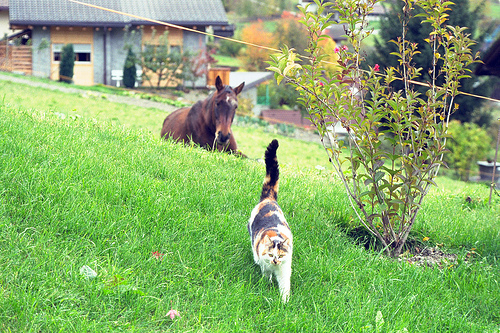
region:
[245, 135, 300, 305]
A black/white/orange cat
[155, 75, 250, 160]
A brown/black horse resting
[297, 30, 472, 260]
A small shrub/bush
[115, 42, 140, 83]
A small pine tree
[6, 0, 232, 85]
A brown/black house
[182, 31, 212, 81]
A small red leaved tree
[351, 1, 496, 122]
A very large pine tree in the backround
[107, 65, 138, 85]
A white bench behind the pine tree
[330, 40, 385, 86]
A few pink flowers on a shrub/bush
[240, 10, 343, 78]
A tree with multiple leaf colors in the backround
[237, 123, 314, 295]
orange black and white cat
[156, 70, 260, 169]
brown and white horse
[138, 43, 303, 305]
horse and cat in green grass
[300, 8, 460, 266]
green bush in green grass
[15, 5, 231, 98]
tan and grey house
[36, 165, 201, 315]
green grass on the ground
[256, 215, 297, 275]
head of a tabby cat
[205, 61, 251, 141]
head of a brown horse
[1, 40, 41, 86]
brown wooden fence attached to a house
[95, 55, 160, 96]
white wooden bench in front of a house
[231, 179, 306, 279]
The cat is calico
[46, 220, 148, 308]
The grass has leaves in it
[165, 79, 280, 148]
The horse is laying down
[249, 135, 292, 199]
The cat's tail is black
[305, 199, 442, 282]
The bush is growing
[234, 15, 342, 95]
The leaves in the tree are many colors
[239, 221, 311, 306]
The cat is walking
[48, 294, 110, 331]
The grass is green and long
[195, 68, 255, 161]
The horse is watching the cat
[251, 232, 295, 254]
The cat has 2 ears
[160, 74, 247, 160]
a horse laying in the grass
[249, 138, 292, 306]
a calico cat walking in the grass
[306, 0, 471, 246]
a bush next to a cat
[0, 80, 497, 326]
a green grassy slope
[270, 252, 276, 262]
a black line on a cat's nose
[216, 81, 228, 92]
a black forelock on a brown horse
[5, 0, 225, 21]
a metal roof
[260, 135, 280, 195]
a black and orange cat tail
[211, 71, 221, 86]
a brown horse ear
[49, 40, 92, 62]
a window on a house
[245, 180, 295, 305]
Small cat walking through grass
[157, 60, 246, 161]
Brown horse laying on grass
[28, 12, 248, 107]
Small building in the background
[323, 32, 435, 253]
Small bush growing in yard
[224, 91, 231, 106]
White spot on horses head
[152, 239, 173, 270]
Small red flowers in lawn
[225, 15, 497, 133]
Tall blurry trees in background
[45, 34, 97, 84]
Orange garage door on building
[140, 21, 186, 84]
Orange garage door on building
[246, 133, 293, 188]
Tall raised bushy cat tail